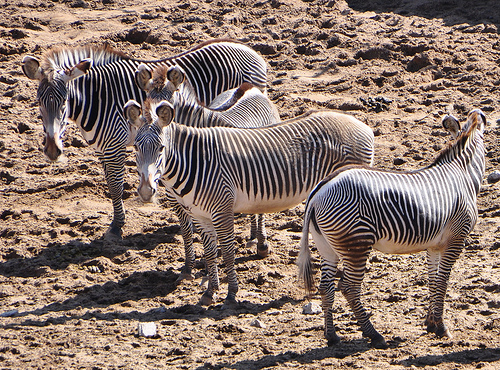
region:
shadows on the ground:
[30, 202, 160, 312]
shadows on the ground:
[22, 233, 152, 344]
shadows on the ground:
[25, 239, 165, 367]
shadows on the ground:
[25, 218, 170, 335]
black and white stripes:
[117, 102, 359, 319]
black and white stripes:
[116, 94, 389, 306]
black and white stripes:
[118, 102, 376, 313]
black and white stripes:
[85, 85, 390, 327]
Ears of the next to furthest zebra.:
[134, 62, 186, 90]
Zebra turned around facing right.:
[291, 109, 487, 344]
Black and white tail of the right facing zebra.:
[293, 205, 317, 295]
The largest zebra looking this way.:
[21, 41, 268, 241]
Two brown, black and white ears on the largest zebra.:
[18, 54, 92, 84]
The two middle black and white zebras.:
[123, 62, 377, 311]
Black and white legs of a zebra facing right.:
[312, 230, 389, 350]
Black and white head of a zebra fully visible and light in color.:
[123, 97, 175, 202]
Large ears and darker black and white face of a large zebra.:
[20, 55, 92, 161]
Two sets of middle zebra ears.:
[123, 65, 185, 129]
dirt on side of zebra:
[330, 227, 374, 271]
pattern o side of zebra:
[372, 186, 443, 223]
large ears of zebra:
[114, 98, 183, 128]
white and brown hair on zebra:
[68, 48, 128, 63]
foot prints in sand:
[68, 276, 161, 312]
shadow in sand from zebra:
[65, 274, 187, 306]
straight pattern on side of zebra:
[242, 135, 296, 195]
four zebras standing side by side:
[52, 34, 465, 278]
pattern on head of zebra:
[139, 134, 156, 164]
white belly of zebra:
[235, 198, 304, 212]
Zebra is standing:
[288, 105, 490, 354]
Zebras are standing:
[14, 28, 491, 351]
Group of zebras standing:
[13, 29, 487, 349]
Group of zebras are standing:
[15, 30, 491, 350]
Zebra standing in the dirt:
[290, 102, 492, 350]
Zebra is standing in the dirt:
[295, 107, 494, 352]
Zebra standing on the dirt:
[290, 107, 493, 349]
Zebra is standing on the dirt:
[285, 102, 490, 357]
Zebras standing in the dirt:
[17, 32, 489, 354]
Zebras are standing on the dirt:
[11, 35, 494, 351]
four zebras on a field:
[3, 4, 493, 361]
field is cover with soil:
[6, 10, 493, 367]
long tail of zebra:
[294, 191, 319, 299]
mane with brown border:
[425, 111, 485, 176]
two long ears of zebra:
[119, 94, 178, 134]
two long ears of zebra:
[130, 56, 189, 100]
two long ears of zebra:
[8, 48, 97, 90]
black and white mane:
[166, 90, 225, 126]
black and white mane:
[48, 36, 140, 63]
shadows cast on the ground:
[11, 234, 161, 337]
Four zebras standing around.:
[18, 39, 483, 360]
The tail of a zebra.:
[278, 173, 347, 305]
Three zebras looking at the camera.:
[21, 46, 243, 218]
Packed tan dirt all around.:
[3, 3, 499, 369]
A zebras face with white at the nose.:
[124, 98, 173, 205]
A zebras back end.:
[297, 162, 404, 364]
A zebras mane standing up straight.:
[28, 36, 139, 83]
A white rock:
[132, 313, 160, 343]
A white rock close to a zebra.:
[299, 293, 321, 318]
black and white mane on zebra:
[42, 42, 119, 62]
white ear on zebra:
[19, 55, 39, 81]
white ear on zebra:
[68, 58, 93, 79]